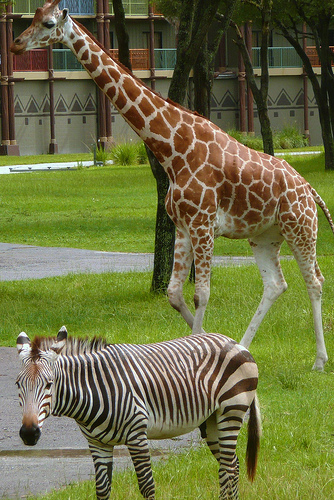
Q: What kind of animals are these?
A: Zebra and giraffe.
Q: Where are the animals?
A: Green field.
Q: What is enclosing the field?
A: Wall.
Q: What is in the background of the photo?
A: Trees.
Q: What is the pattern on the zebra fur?
A: Stripes.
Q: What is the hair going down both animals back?
A: Mane.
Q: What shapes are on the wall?
A: Triangles.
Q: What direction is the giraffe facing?
A: Left.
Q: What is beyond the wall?
A: Building with balconies.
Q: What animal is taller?
A: Giraffe.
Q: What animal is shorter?
A: Zebra.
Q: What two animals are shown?
A: Zebra and giraffe.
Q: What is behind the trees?
A: Building.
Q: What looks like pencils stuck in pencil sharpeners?
A: Wood poles.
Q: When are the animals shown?
A: Daytime.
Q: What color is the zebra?
A: Black and white.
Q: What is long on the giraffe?
A: Neck.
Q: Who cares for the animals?
A: Zookeeper.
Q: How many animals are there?
A: Two.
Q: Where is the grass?
A: Ground.